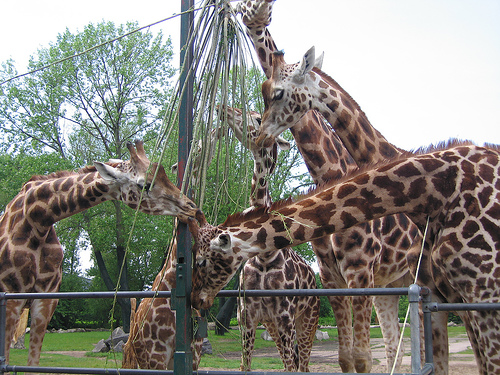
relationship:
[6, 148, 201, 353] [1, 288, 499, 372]
giraffe in enclosure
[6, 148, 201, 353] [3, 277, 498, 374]
giraffe in enclosure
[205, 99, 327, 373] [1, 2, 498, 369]
giraffe in enclosure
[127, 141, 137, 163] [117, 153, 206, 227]
horn on head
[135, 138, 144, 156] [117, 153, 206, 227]
horn on head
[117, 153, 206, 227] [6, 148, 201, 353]
head of giraffe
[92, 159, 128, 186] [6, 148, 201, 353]
ear of giraffe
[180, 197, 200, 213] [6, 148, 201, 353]
nose of giraffe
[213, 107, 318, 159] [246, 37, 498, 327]
mouth of giraffe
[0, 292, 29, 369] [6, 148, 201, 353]
leg of giraffe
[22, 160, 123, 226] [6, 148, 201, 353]
neck of giraffe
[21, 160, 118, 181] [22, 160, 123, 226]
mane on neck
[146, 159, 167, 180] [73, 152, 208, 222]
bump in head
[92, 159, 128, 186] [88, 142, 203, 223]
ear on side of head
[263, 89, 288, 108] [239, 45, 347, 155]
eye on side of head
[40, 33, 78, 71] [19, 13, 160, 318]
leaves on tree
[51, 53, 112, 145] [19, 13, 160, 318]
branches of tree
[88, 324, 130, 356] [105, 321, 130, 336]
rocks have a top